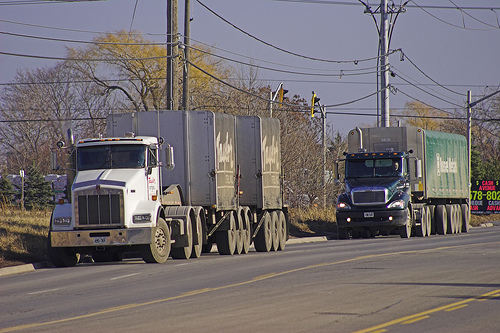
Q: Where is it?
A: This is at the road.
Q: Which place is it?
A: It is a road.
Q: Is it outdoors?
A: Yes, it is outdoors.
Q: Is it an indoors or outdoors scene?
A: It is outdoors.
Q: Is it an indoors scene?
A: No, it is outdoors.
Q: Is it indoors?
A: No, it is outdoors.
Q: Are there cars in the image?
A: No, there are no cars.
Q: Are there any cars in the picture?
A: No, there are no cars.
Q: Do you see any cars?
A: No, there are no cars.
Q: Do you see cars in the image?
A: No, there are no cars.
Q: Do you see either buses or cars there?
A: No, there are no cars or buses.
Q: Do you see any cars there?
A: No, there are no cars.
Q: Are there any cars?
A: No, there are no cars.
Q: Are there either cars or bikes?
A: No, there are no cars or bikes.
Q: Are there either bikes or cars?
A: No, there are no cars or bikes.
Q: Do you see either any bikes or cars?
A: No, there are no cars or bikes.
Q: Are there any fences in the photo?
A: No, there are no fences.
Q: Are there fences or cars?
A: No, there are no fences or cars.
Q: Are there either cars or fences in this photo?
A: No, there are no fences or cars.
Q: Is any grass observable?
A: Yes, there is grass.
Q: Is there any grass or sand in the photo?
A: Yes, there is grass.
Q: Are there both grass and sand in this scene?
A: No, there is grass but no sand.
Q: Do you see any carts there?
A: No, there are no carts.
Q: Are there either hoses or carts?
A: No, there are no carts or hoses.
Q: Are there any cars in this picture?
A: No, there are no cars.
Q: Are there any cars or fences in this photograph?
A: No, there are no cars or fences.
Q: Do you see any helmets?
A: No, there are no helmets.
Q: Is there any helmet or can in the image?
A: No, there are no helmets or cans.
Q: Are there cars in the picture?
A: No, there are no cars.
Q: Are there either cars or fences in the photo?
A: No, there are no cars or fences.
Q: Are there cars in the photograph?
A: No, there are no cars.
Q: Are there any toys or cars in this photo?
A: No, there are no cars or toys.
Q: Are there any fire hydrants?
A: No, there are no fire hydrants.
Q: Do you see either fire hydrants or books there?
A: No, there are no fire hydrants or books.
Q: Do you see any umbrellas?
A: No, there are no umbrellas.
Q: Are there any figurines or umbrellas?
A: No, there are no umbrellas or figurines.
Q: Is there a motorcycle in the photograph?
A: No, there are no motorcycles.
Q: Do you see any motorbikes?
A: No, there are no motorbikes.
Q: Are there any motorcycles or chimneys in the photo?
A: No, there are no motorcycles or chimneys.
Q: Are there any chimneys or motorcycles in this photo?
A: No, there are no motorcycles or chimneys.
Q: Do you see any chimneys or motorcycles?
A: No, there are no motorcycles or chimneys.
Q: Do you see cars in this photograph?
A: No, there are no cars.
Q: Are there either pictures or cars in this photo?
A: No, there are no cars or pictures.